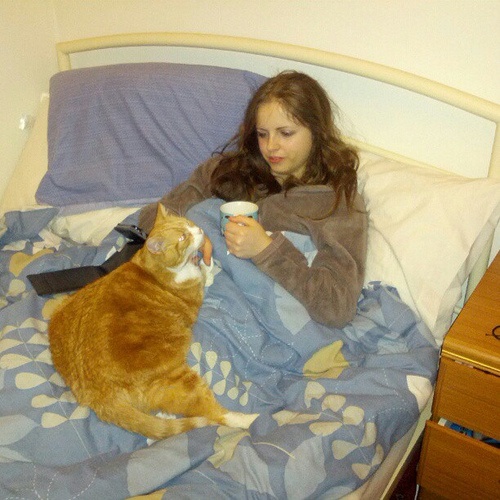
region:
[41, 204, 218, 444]
A fat cat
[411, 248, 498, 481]
wooden night stand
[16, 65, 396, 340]
A lady holding a cup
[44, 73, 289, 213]
Blue pillow on the bed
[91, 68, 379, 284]
A woman wearing a brown fleece top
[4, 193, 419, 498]
Blue comforter with white design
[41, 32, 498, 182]
White and creme headboard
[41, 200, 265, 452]
a cat on the bed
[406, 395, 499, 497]
Slightly opened nightstand drawer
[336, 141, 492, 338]
Off white pillow underneath the lady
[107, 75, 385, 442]
sick woman laying in bed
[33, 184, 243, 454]
large tabby laying on bed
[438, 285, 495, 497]
wooden cabinet next to bed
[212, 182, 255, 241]
coffee mug in girl's hand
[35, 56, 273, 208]
large blue pillow on bed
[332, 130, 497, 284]
large white pillow on bed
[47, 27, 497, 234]
white bed post of bed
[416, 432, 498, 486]
slightly open wood cabinet drawer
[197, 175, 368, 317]
gray sweater on woman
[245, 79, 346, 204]
long brown hair on woman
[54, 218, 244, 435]
A big brown cat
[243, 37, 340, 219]
A woman in bed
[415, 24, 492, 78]
A white bedroom wall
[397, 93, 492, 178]
A white bedroom wall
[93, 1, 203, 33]
A white bedroom wall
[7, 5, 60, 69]
A white bedroom wall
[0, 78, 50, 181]
A white bedroom wall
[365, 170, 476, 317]
A white bedroom bedsheet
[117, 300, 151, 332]
the cat is orange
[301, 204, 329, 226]
the sweater is brown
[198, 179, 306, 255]
she is covered up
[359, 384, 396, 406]
the blanket is blue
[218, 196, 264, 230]
she is holding a cup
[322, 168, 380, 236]
she is laying on a pillow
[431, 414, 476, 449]
the drawer is open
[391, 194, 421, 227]
the pillow is white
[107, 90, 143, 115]
the pillow is blue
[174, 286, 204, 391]
the cat is laying down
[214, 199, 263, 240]
a woman with a cup in her hand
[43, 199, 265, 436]
an orange cat on a bed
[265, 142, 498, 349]
a white pillow on a bed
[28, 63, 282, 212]
a blue pillow on a bed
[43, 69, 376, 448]
a woman on a bed with a cat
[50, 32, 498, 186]
a white and cream colored headboard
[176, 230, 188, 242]
the eye of a cat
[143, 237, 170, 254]
the ear of a cat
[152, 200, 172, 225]
the ear of a cat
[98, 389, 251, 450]
the tail of a cat